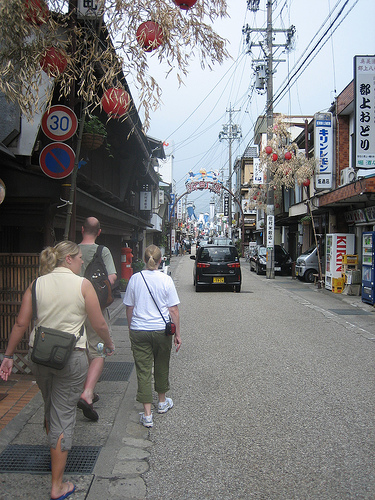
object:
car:
[189, 244, 243, 293]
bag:
[29, 274, 86, 371]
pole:
[264, 0, 276, 279]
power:
[232, 1, 297, 96]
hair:
[35, 238, 80, 279]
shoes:
[157, 395, 175, 415]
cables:
[162, 14, 269, 147]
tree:
[0, 0, 237, 142]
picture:
[0, 0, 375, 499]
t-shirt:
[121, 267, 181, 333]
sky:
[102, 0, 375, 219]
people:
[0, 238, 117, 500]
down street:
[141, 254, 374, 500]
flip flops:
[46, 477, 80, 500]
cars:
[248, 242, 294, 277]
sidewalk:
[249, 272, 374, 366]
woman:
[121, 243, 184, 428]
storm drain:
[0, 441, 104, 474]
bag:
[82, 243, 115, 310]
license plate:
[212, 277, 226, 284]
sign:
[40, 103, 80, 144]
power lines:
[236, 2, 324, 98]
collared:
[50, 266, 74, 275]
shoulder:
[90, 239, 111, 261]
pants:
[128, 328, 173, 404]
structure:
[168, 179, 245, 259]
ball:
[100, 85, 131, 120]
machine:
[324, 232, 356, 292]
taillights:
[196, 262, 211, 269]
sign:
[37, 139, 77, 181]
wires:
[270, 0, 344, 104]